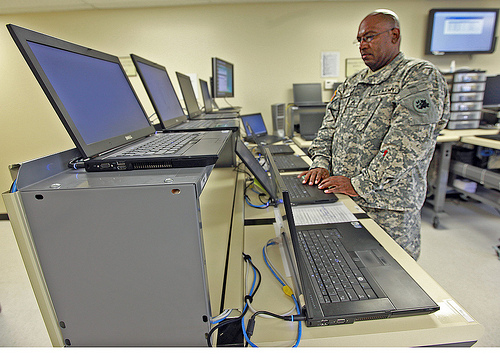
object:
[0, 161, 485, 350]
stand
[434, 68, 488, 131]
bin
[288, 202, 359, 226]
paper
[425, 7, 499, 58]
tv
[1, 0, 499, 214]
wall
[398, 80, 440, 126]
patch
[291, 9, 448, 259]
member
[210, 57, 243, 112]
desktop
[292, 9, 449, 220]
military member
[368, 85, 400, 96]
tag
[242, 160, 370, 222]
desk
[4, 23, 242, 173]
laptop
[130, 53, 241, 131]
laptop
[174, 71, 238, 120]
laptop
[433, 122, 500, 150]
table